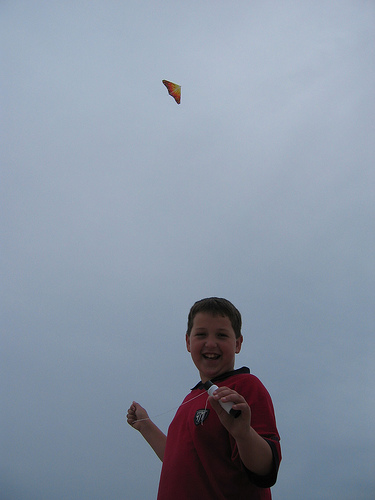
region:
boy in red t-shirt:
[156, 296, 283, 497]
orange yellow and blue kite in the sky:
[162, 79, 183, 104]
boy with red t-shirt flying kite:
[155, 291, 278, 491]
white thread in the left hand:
[203, 381, 237, 420]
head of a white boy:
[186, 297, 243, 374]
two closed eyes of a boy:
[192, 327, 233, 339]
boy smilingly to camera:
[155, 292, 279, 494]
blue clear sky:
[1, 3, 371, 496]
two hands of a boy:
[127, 384, 271, 471]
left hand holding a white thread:
[212, 378, 284, 469]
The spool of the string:
[205, 382, 239, 417]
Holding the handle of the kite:
[199, 371, 244, 423]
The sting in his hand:
[106, 399, 151, 433]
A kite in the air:
[155, 56, 191, 113]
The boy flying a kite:
[121, 62, 305, 494]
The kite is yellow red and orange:
[161, 73, 186, 111]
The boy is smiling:
[173, 287, 249, 373]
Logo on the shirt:
[189, 401, 212, 426]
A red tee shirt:
[159, 359, 288, 498]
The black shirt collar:
[181, 364, 250, 395]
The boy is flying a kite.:
[140, 237, 272, 437]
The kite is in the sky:
[142, 52, 210, 132]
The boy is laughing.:
[177, 315, 255, 387]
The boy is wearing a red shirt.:
[164, 368, 278, 493]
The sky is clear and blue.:
[91, 31, 338, 191]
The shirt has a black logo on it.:
[179, 401, 207, 434]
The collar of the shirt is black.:
[183, 377, 254, 388]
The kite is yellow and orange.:
[150, 59, 209, 121]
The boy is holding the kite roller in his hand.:
[197, 382, 246, 413]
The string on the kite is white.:
[202, 368, 234, 423]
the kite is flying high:
[33, 79, 234, 280]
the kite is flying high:
[137, 12, 213, 104]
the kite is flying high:
[170, 67, 203, 170]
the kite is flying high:
[121, 36, 203, 123]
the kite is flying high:
[132, 52, 228, 151]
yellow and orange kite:
[155, 70, 188, 118]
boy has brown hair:
[185, 292, 253, 344]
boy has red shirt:
[188, 373, 279, 486]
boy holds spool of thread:
[211, 384, 247, 420]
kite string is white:
[199, 378, 238, 432]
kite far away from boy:
[153, 72, 188, 116]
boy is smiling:
[148, 301, 268, 474]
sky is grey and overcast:
[24, 44, 98, 256]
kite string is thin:
[132, 382, 208, 429]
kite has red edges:
[152, 72, 184, 108]